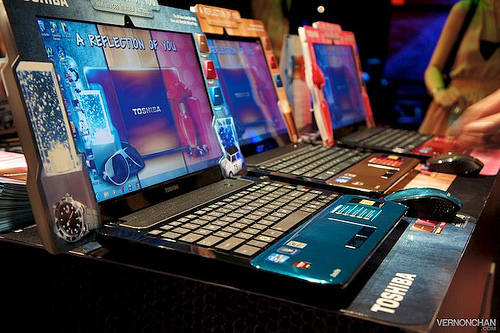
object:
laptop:
[0, 0, 411, 292]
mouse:
[382, 186, 464, 224]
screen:
[33, 12, 227, 205]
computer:
[296, 19, 471, 159]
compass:
[49, 191, 102, 244]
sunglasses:
[100, 143, 146, 186]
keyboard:
[145, 178, 340, 258]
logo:
[370, 271, 419, 316]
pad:
[340, 211, 479, 329]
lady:
[417, 0, 499, 136]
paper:
[0, 150, 29, 185]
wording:
[75, 32, 178, 52]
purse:
[421, 0, 478, 123]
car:
[210, 101, 249, 180]